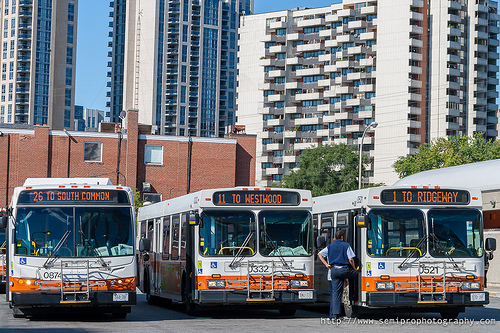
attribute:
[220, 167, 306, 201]
digital board — 11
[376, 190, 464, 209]
digital board — 1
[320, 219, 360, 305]
man — wearing blue, talking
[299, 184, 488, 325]
bus — 1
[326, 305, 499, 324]
website — photographer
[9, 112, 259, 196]
building — brick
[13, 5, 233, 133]
buildings — similar, tall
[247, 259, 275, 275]
number — 0332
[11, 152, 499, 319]
buses — together, parked, white, aligned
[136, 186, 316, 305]
bus — 11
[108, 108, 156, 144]
chimney — brick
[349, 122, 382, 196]
pole — light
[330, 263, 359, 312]
pants — blue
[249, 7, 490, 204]
buildings — apartments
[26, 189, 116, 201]
digital board — 26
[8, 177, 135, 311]
bus — is the furthest, 26